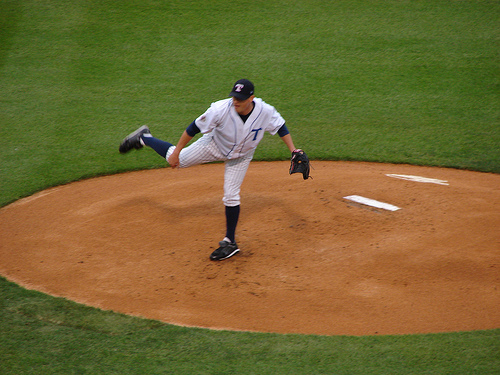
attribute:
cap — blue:
[222, 50, 264, 107]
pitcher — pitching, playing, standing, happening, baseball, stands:
[74, 46, 362, 298]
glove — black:
[282, 144, 325, 181]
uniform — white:
[158, 99, 309, 212]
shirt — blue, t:
[184, 101, 206, 137]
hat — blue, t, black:
[235, 76, 258, 103]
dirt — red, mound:
[146, 214, 217, 272]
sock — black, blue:
[216, 201, 262, 256]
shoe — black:
[107, 113, 163, 159]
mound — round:
[344, 150, 424, 226]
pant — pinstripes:
[163, 151, 252, 228]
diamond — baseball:
[304, 156, 481, 266]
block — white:
[323, 173, 416, 236]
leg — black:
[194, 175, 275, 268]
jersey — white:
[179, 88, 299, 184]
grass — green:
[186, 11, 330, 81]